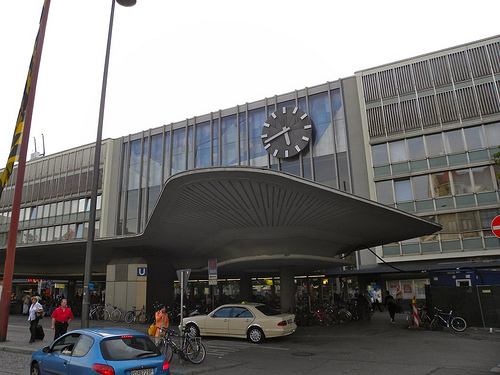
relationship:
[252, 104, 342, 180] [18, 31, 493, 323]
clock on side of shopping center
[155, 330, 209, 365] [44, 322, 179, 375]
bikes near car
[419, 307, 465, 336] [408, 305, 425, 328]
bike near cone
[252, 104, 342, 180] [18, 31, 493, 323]
clock on front of shopping center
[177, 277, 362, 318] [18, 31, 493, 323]
doors lead into shopping center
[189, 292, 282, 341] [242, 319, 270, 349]
car has wheels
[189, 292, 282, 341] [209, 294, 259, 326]
car has windows